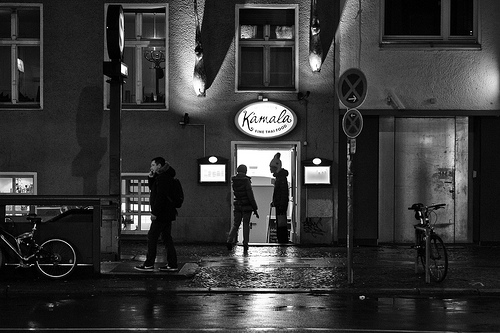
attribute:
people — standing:
[133, 149, 300, 251]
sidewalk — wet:
[159, 246, 447, 294]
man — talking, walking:
[140, 155, 197, 270]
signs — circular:
[335, 71, 367, 142]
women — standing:
[227, 165, 257, 248]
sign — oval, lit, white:
[235, 100, 302, 145]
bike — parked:
[402, 195, 455, 284]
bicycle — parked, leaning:
[7, 211, 99, 285]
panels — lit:
[182, 147, 229, 204]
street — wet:
[50, 282, 489, 330]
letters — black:
[248, 112, 287, 129]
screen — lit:
[296, 168, 345, 181]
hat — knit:
[266, 152, 283, 167]